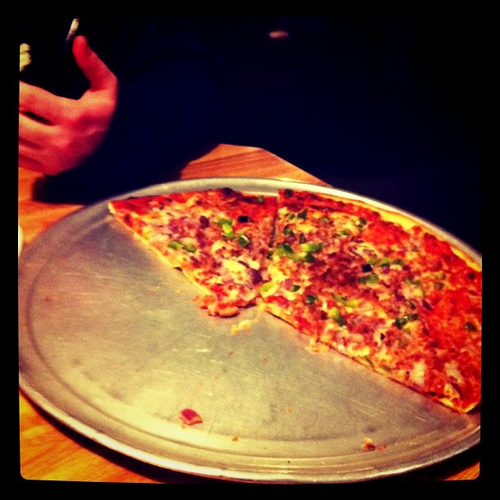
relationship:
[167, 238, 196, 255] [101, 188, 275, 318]
pepper on pizza slice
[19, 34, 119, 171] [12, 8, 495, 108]
hand in background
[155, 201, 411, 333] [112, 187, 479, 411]
peppers are on pizza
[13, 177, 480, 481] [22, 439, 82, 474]
pan under table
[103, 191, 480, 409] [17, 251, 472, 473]
half pizza on pan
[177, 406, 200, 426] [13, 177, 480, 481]
topping on pan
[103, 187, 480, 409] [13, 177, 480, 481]
half pizza on pan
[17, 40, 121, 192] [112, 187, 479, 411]
hand near pizza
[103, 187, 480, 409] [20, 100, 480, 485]
half pizza on pizza pan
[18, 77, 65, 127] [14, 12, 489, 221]
pointer finger on human